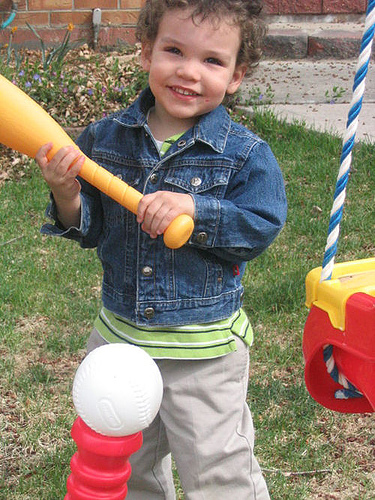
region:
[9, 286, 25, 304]
green grass on ground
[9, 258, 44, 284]
green grass on ground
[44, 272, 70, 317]
green grass on ground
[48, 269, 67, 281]
green grass on ground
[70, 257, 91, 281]
green grass on ground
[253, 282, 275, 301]
green grass on ground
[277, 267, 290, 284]
green grass on ground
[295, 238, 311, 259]
green grass on ground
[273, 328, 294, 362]
green grass on ground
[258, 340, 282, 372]
green grass on ground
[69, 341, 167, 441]
Big white ball with light design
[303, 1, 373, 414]
Side of swing hanging from blue and white rope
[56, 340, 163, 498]
Plastic red toy holding ball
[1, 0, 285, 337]
Boy holding plastic yellow bat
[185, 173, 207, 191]
Silver button on chest pocket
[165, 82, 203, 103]
Smile of child showing teeth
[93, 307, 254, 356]
Green striped shirt under jacket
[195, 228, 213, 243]
Round button on the wrist of jacket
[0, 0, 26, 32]
Part of a water hose in the back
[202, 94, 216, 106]
Red mark on the face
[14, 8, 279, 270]
a child playing wiffle ball in the yard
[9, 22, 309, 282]
this boy is holding a bat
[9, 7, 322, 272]
he is about to swing the bat at the ball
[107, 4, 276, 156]
the child looks happy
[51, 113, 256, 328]
he has on a blue jean jacket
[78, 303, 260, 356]
his shirt is green with white and black stripes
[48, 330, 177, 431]
the ball is white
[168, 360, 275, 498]
he is wearing khaki pants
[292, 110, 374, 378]
a toy is in the background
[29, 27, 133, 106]
flowers on the ground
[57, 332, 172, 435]
white baseball bat on the tee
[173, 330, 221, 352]
green and white stripe shirt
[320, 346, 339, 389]
blue and white rope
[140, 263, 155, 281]
button on the jean jacket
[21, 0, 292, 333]
boy holding a bat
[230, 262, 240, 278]
tag on the jacket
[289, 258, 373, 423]
swing on a rope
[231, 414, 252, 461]
line down the pants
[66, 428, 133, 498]
red tee for the ball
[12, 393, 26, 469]
patch of dirt on the ground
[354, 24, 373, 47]
The line is blue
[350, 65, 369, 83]
The line is blue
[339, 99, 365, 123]
The line is blue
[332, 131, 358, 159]
The line is blue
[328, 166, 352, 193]
The line is blue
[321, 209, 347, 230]
The line is blue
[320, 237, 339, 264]
The line is blue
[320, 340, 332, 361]
The line is blue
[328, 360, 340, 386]
The line is blue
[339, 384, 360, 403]
The line is blue